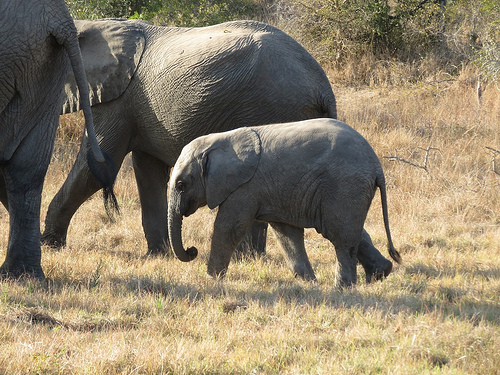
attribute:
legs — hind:
[327, 210, 391, 287]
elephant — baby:
[164, 115, 405, 290]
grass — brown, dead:
[1, 70, 484, 373]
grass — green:
[358, 3, 406, 53]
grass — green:
[316, 16, 410, 36]